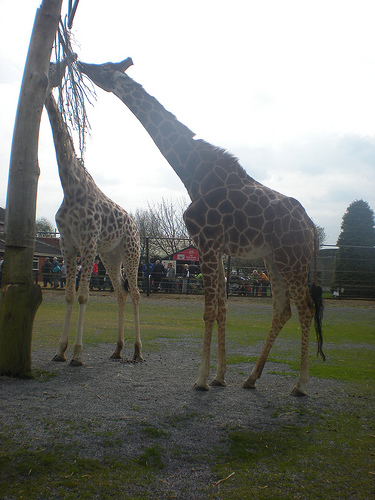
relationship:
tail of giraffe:
[310, 222, 326, 365] [78, 59, 328, 389]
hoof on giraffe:
[48, 349, 66, 363] [42, 51, 142, 370]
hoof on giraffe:
[61, 357, 86, 366] [42, 51, 142, 370]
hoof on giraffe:
[109, 349, 120, 359] [42, 51, 142, 370]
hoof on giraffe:
[131, 351, 147, 366] [42, 51, 142, 370]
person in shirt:
[257, 267, 268, 294] [260, 273, 268, 281]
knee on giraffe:
[76, 294, 86, 304] [37, 85, 141, 365]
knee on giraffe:
[65, 292, 73, 304] [37, 85, 141, 365]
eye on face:
[100, 62, 108, 70] [77, 62, 124, 87]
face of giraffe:
[77, 62, 124, 87] [78, 59, 328, 389]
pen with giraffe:
[0, 290, 355, 498] [45, 90, 145, 366]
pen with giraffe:
[0, 290, 355, 498] [78, 59, 328, 389]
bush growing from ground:
[333, 199, 373, 296] [35, 290, 355, 461]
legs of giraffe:
[195, 254, 227, 399] [78, 59, 328, 389]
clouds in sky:
[5, 9, 362, 229] [0, 2, 361, 239]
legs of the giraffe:
[242, 254, 321, 397] [78, 59, 328, 389]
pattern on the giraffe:
[86, 199, 106, 229] [42, 51, 142, 370]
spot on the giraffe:
[200, 250, 217, 265] [78, 59, 328, 389]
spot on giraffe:
[204, 272, 210, 289] [78, 59, 328, 389]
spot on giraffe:
[207, 287, 217, 295] [78, 59, 328, 389]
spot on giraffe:
[271, 244, 290, 268] [78, 59, 328, 389]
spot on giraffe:
[292, 259, 303, 273] [78, 59, 328, 389]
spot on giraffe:
[230, 205, 249, 233] [78, 59, 328, 389]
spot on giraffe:
[201, 222, 226, 241] [78, 59, 328, 389]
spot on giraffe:
[185, 197, 208, 226] [78, 59, 328, 389]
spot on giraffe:
[304, 227, 316, 244] [75, 53, 337, 407]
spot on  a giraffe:
[201, 221, 225, 242] [78, 59, 328, 389]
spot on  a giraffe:
[220, 213, 232, 230] [78, 59, 328, 389]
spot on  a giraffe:
[231, 207, 246, 232] [78, 59, 328, 389]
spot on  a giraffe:
[243, 224, 259, 241] [78, 59, 328, 389]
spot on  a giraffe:
[247, 209, 265, 232] [78, 59, 328, 389]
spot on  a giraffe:
[227, 188, 247, 209] [78, 59, 328, 389]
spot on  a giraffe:
[272, 245, 289, 266] [78, 59, 328, 389]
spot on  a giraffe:
[284, 267, 294, 279] [78, 59, 328, 389]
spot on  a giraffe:
[295, 284, 305, 301] [78, 59, 328, 389]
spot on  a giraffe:
[247, 192, 260, 204] [78, 59, 328, 389]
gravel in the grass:
[10, 351, 299, 452] [41, 323, 349, 479]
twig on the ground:
[210, 464, 237, 488] [23, 404, 353, 488]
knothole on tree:
[29, 279, 46, 316] [2, 0, 77, 382]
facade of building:
[157, 243, 202, 265] [152, 245, 207, 300]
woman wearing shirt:
[49, 260, 63, 291] [49, 266, 61, 276]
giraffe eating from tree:
[78, 59, 328, 389] [1, 1, 69, 384]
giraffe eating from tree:
[34, 50, 150, 372] [1, 1, 69, 384]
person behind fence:
[193, 267, 203, 292] [30, 270, 338, 297]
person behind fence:
[180, 261, 192, 295] [30, 270, 338, 297]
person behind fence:
[151, 259, 165, 290] [30, 270, 338, 297]